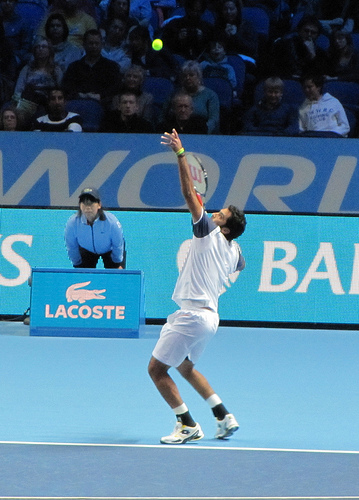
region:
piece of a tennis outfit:
[153, 419, 201, 445]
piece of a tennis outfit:
[204, 412, 241, 439]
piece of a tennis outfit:
[166, 398, 197, 427]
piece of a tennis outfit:
[204, 386, 230, 417]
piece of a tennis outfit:
[148, 302, 220, 371]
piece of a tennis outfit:
[171, 294, 218, 318]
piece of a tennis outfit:
[167, 203, 243, 314]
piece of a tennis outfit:
[168, 140, 184, 156]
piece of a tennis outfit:
[60, 206, 125, 264]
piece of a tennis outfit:
[63, 243, 134, 268]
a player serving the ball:
[108, 28, 276, 470]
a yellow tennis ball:
[146, 37, 165, 55]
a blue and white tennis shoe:
[153, 423, 207, 445]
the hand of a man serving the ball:
[129, 36, 193, 156]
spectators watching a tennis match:
[10, 8, 350, 132]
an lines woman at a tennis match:
[29, 181, 142, 273]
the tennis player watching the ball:
[207, 198, 248, 240]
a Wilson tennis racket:
[182, 153, 207, 206]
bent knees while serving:
[136, 344, 211, 388]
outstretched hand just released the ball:
[146, 36, 188, 153]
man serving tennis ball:
[167, 230, 243, 413]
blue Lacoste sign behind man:
[38, 323, 82, 336]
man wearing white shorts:
[162, 322, 204, 340]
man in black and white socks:
[163, 394, 197, 436]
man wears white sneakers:
[198, 408, 251, 450]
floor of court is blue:
[294, 423, 322, 434]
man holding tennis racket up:
[175, 145, 213, 196]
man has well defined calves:
[151, 382, 184, 396]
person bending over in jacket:
[55, 220, 146, 264]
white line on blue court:
[285, 444, 322, 460]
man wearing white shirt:
[135, 126, 244, 440]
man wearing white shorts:
[145, 128, 258, 449]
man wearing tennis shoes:
[151, 126, 255, 444]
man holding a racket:
[143, 126, 252, 452]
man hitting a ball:
[136, 125, 253, 448]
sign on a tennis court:
[24, 257, 138, 347]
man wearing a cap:
[59, 185, 136, 265]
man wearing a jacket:
[59, 186, 132, 263]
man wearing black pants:
[54, 188, 125, 262]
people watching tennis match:
[205, 44, 346, 127]